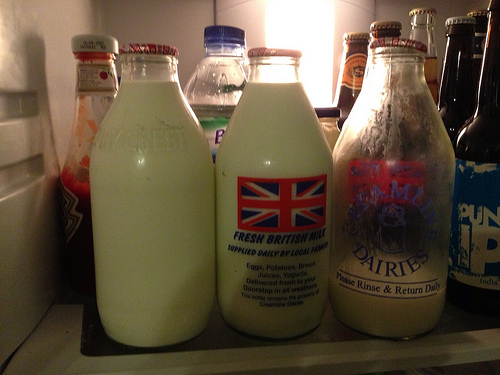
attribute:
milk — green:
[99, 43, 212, 313]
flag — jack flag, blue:
[233, 173, 326, 230]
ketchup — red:
[57, 25, 93, 239]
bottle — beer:
[437, 14, 475, 118]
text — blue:
[231, 228, 326, 252]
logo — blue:
[221, 229, 329, 310]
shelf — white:
[30, 338, 499, 369]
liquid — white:
[128, 173, 181, 208]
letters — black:
[240, 260, 321, 314]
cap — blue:
[199, 24, 247, 55]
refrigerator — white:
[1, 1, 64, 310]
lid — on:
[364, 35, 429, 55]